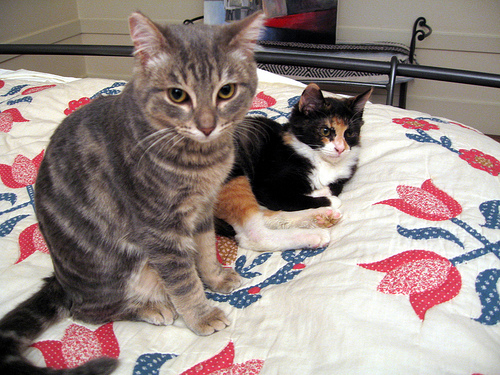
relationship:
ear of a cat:
[124, 11, 169, 61] [0, 8, 264, 373]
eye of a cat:
[162, 85, 191, 105] [0, 8, 264, 373]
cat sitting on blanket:
[0, 8, 264, 373] [2, 20, 499, 373]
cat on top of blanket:
[0, 8, 264, 373] [2, 20, 499, 373]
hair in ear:
[133, 17, 157, 54] [128, 10, 173, 57]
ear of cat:
[128, 10, 173, 57] [0, 8, 264, 373]